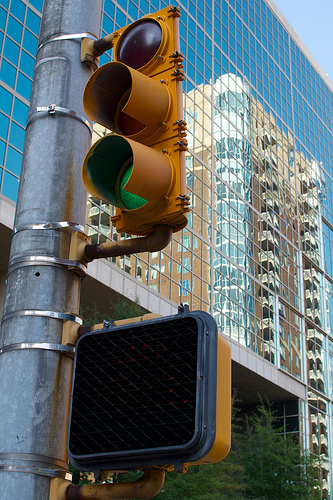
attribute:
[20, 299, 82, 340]
band — silver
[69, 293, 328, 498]
tree — green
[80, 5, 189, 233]
traffic light — green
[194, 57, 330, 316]
windows — reflective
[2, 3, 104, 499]
pole — silver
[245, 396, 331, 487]
plant — green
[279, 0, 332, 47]
sky — clear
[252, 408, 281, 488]
plants — small, green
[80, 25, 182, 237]
signal — yellow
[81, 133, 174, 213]
traffic light — green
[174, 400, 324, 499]
trees — green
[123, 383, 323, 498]
tree tops — dark, green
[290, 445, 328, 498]
plants — green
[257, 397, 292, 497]
plants — green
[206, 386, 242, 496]
plants — green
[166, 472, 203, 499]
plants — green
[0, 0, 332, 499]
building — glass, tall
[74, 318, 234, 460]
sign — red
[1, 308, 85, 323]
clip — metal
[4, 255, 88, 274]
clip — metal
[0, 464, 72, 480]
clip — metal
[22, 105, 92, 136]
clip — metal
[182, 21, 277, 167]
building — square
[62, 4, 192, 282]
traffic signal — orange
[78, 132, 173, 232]
green light — on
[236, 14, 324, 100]
building — white, brown, colored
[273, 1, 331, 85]
sky — white 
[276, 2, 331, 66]
sky — light blue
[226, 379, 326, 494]
plants — green 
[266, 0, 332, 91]
sky — blue